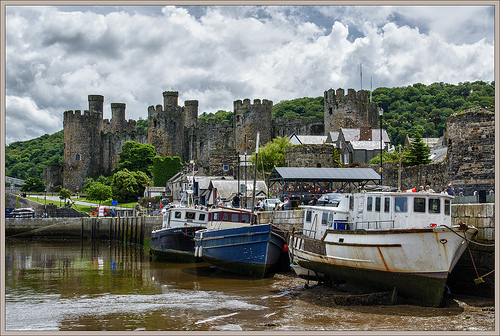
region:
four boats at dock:
[137, 171, 474, 296]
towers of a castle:
[54, 76, 425, 183]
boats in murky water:
[1, 186, 493, 333]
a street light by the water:
[369, 90, 391, 210]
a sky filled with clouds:
[0, 1, 491, 146]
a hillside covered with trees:
[0, 60, 497, 220]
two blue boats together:
[110, 176, 287, 284]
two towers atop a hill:
[352, 57, 375, 111]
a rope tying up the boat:
[435, 213, 498, 256]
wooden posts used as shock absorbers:
[94, 212, 151, 251]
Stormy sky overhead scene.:
[153, 10, 443, 75]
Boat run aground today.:
[291, 195, 481, 313]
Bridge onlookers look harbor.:
[381, 174, 481, 214]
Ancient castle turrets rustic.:
[59, 85, 133, 186]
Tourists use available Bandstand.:
[263, 161, 403, 211]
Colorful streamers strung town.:
[327, 100, 492, 155]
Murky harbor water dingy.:
[14, 225, 241, 332]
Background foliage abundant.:
[7, 110, 97, 201]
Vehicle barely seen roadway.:
[6, 199, 64, 231]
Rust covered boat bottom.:
[292, 239, 478, 298]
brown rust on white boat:
[372, 250, 392, 265]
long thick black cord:
[436, 221, 493, 270]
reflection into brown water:
[27, 253, 72, 285]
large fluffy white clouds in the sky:
[140, 16, 328, 66]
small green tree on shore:
[57, 185, 81, 201]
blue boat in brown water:
[187, 218, 284, 273]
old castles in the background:
[44, 88, 300, 149]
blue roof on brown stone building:
[275, 162, 350, 187]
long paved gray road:
[37, 189, 102, 208]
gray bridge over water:
[46, 210, 186, 244]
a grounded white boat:
[298, 189, 448, 286]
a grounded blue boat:
[194, 197, 281, 269]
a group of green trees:
[374, 82, 498, 142]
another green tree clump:
[272, 103, 322, 138]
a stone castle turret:
[231, 97, 271, 157]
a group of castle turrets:
[149, 90, 196, 164]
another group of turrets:
[61, 90, 123, 196]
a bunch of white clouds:
[0, 2, 487, 89]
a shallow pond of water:
[0, 236, 173, 327]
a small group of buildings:
[266, 123, 384, 158]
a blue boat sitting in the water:
[200, 206, 277, 273]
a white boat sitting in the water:
[293, 185, 460, 285]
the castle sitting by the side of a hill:
[51, 93, 386, 182]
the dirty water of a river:
[10, 233, 495, 334]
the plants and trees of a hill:
[17, 83, 493, 165]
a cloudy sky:
[9, 7, 486, 119]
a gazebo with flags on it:
[256, 165, 380, 200]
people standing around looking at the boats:
[411, 182, 453, 202]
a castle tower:
[60, 111, 102, 194]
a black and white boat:
[148, 197, 204, 262]